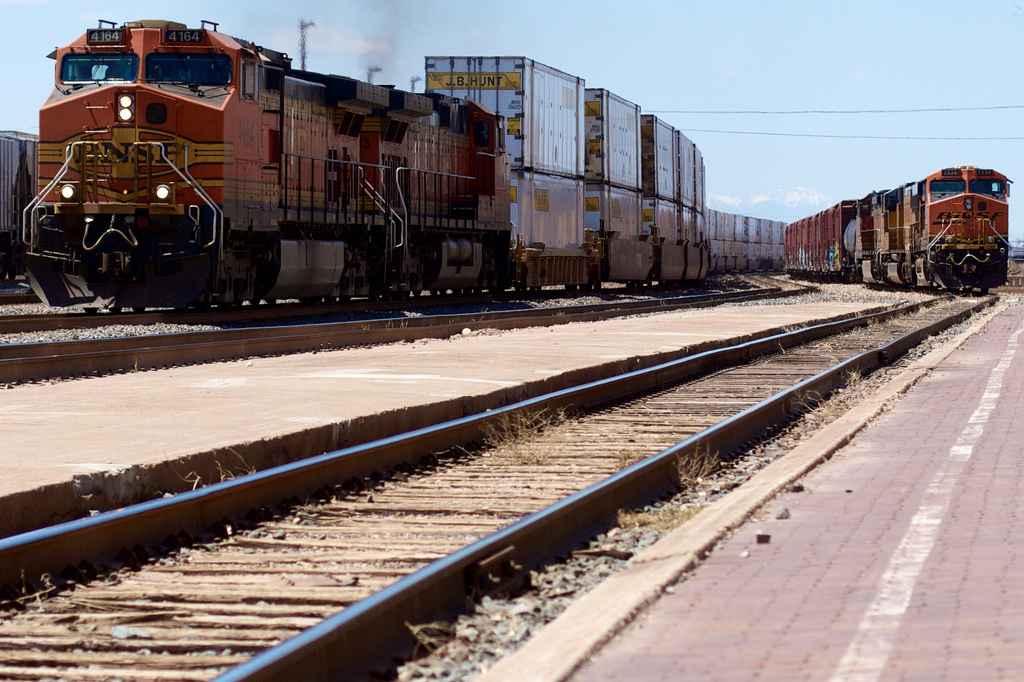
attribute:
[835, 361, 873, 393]
plant — DEAD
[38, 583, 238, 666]
woods — broken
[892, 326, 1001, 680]
dash — white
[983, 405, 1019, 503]
bricks — red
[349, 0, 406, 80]
smoke — black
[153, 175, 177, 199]
lights — rounded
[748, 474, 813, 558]
stones — small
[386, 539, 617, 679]
stones — small, gray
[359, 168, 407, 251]
handle bars — white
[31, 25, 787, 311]
train — orange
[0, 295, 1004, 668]
train tracks — gray, metal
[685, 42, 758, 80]
clouds — white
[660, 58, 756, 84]
white clouds — blue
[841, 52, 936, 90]
white skys — blue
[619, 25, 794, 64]
clouds — white